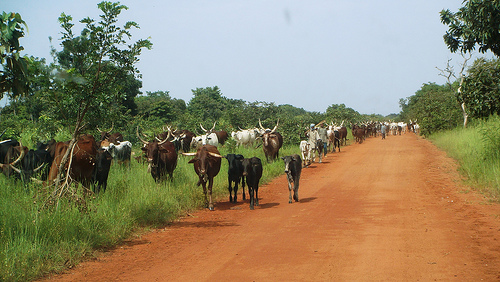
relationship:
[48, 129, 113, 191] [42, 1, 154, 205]
cow standing underneath tree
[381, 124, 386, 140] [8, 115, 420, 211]
man walking cattle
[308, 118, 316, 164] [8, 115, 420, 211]
man walking cattle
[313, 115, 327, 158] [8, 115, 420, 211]
man walking cattle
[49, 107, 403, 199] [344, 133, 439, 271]
cattle on road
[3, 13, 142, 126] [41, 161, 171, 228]
trees on grass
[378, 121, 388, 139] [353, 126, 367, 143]
man walking with cattle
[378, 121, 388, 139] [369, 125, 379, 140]
man walking with cattle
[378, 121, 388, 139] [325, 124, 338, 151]
man walking with cattle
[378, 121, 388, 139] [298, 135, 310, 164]
man walking with cattle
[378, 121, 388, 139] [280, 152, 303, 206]
man walking with cattle